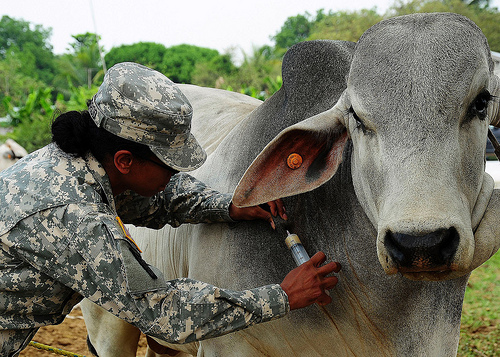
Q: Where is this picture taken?
A: A field.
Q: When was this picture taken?
A: Daytime.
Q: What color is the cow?
A: Grey.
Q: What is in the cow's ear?
A: A tag.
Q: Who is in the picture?
A: A woman.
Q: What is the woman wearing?
A: Fatigues.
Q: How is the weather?
A: Clear.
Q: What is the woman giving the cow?
A: A shot.